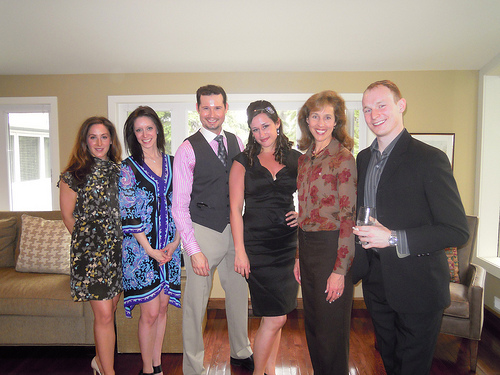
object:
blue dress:
[119, 151, 184, 318]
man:
[349, 77, 470, 373]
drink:
[353, 207, 373, 244]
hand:
[352, 214, 391, 248]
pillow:
[15, 215, 74, 271]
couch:
[0, 205, 127, 344]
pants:
[297, 229, 358, 374]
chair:
[382, 201, 484, 371]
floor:
[279, 322, 305, 374]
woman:
[224, 98, 303, 373]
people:
[53, 81, 468, 373]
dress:
[58, 150, 126, 298]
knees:
[145, 305, 157, 322]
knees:
[157, 297, 168, 314]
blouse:
[298, 141, 357, 275]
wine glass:
[351, 206, 384, 247]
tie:
[214, 135, 228, 164]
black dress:
[232, 147, 304, 317]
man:
[176, 85, 251, 375]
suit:
[355, 128, 470, 374]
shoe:
[84, 356, 104, 373]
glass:
[358, 208, 370, 225]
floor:
[362, 332, 374, 360]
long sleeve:
[168, 125, 248, 256]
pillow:
[439, 240, 462, 279]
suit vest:
[186, 130, 238, 231]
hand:
[284, 207, 300, 230]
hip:
[279, 204, 299, 239]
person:
[56, 114, 124, 373]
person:
[118, 105, 182, 373]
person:
[295, 88, 355, 373]